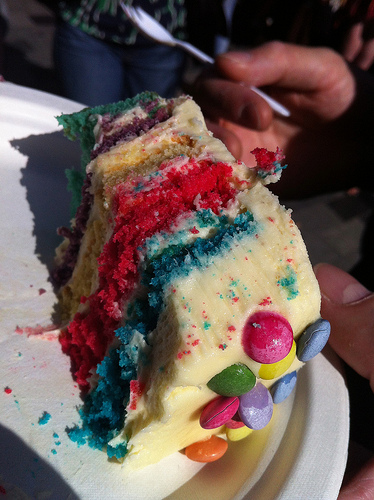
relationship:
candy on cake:
[252, 321, 292, 361] [45, 90, 330, 468]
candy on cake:
[211, 366, 254, 393] [45, 90, 330, 468]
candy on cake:
[295, 319, 332, 362] [45, 90, 330, 468]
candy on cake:
[273, 373, 295, 403] [45, 90, 330, 468]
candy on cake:
[240, 383, 274, 429] [45, 90, 330, 468]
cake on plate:
[45, 90, 330, 468] [3, 78, 359, 498]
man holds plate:
[203, 9, 373, 498] [1, 76, 184, 302]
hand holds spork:
[202, 45, 364, 187] [124, 5, 292, 120]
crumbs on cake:
[30, 408, 88, 456] [50, 115, 339, 337]